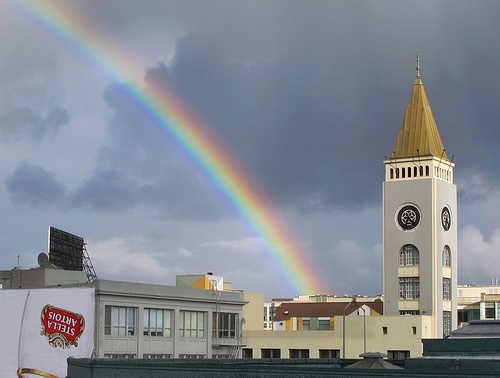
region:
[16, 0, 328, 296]
A colorful rainbow in the sky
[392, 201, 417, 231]
A black clock on a clock tower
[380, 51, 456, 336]
A clock tower with a gold roof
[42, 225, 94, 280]
A large billboard on top of a roof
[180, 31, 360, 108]
dark clouds in the sky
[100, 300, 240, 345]
windows at the top of a building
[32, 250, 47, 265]
A satellite on top of a roof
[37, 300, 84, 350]
A red logo on the side of a building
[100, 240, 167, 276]
White clouds above a roof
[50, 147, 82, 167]
blue sky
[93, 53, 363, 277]
rainbow shone in sky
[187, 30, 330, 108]
cloudy gray blue sky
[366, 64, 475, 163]
gold diamond shape steeple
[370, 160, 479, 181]
white see through window of church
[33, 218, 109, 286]
black empty billboard sign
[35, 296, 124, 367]
stella artois white and red painting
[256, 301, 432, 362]
square flat beige building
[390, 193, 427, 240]
fancy black and white clock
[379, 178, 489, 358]
tall gray church building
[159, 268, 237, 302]
geometric colored roof top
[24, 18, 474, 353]
A rainbow in an urban setting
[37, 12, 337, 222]
A rainbow in a cloudy sky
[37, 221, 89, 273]
The back of a billboard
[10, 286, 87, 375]
A beer ad on a building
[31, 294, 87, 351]
An upside down product ad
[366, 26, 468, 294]
A steeple against a cloudy sky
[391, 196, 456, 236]
Two visible clocks in a tower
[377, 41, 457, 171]
The steeple part of a twoer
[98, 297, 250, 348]
Four windows in a building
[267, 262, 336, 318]
Buildings and a rainbow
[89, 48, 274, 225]
rainbow in cloudy sky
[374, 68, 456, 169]
gold steeple on clock tower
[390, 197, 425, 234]
clock with black hands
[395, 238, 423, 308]
arched window on tower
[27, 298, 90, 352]
upside down logo on wall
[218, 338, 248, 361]
fire escape on building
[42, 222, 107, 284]
back of billboard on roof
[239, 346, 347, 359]
top of a row of windows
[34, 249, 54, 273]
satellite dish on roof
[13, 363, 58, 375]
gold rim on bottle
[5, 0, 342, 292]
A rainbow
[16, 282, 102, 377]
Part of a Stella Artois billboard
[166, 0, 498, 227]
A cloudy sky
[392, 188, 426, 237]
black and grey art on a wall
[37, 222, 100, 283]
The back side of a billboard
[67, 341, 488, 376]
The top of a roof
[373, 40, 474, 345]
A tall grey tower with a yellow roof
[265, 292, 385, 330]
A building with a brown roof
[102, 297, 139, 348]
Large rectangular and square windows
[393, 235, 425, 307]
Arched windows